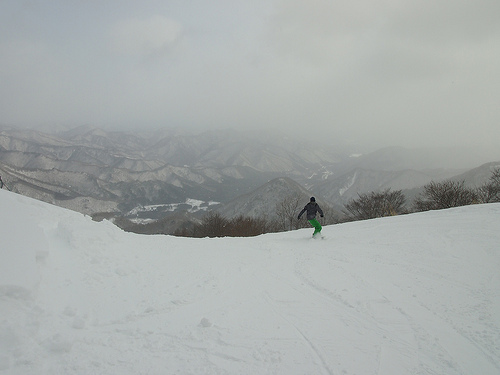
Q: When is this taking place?
A: Daytime.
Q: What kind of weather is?
A: Winter.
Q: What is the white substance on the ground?
A: Snow.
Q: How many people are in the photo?
A: One.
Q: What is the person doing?
A: Skiing.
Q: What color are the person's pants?
A: Green.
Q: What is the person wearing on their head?
A: Hat.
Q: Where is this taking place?
A: The mountains.